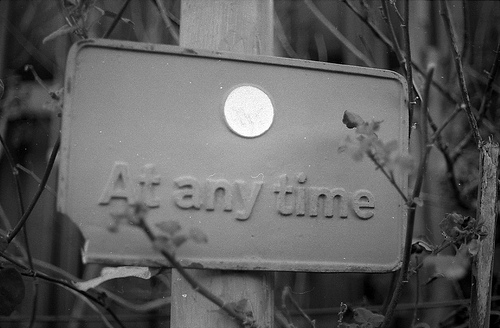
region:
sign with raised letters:
[32, 25, 457, 290]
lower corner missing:
[50, 190, 95, 275]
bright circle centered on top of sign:
[200, 80, 282, 142]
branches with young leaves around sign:
[26, 36, 466, 301]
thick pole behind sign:
[155, 6, 315, 316]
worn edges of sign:
[65, 32, 420, 277]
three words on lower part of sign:
[97, 155, 379, 230]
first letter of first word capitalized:
[95, 155, 375, 230]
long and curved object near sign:
[460, 122, 496, 319]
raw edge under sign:
[58, 250, 165, 295]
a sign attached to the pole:
[54, 29, 416, 281]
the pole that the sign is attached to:
[163, 0, 300, 327]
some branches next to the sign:
[321, 7, 478, 324]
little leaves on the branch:
[99, 196, 197, 260]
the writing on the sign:
[89, 155, 379, 227]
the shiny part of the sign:
[220, 80, 280, 144]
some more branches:
[16, 148, 158, 326]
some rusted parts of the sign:
[68, 36, 208, 61]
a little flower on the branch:
[333, 289, 375, 326]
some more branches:
[51, 9, 192, 44]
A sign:
[73, 70, 343, 262]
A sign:
[168, 129, 328, 314]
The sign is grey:
[51, 29, 424, 294]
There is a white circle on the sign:
[208, 69, 268, 150]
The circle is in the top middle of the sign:
[211, 74, 291, 162]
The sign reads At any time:
[92, 140, 389, 254]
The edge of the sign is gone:
[41, 122, 160, 282]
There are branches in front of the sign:
[347, 15, 489, 312]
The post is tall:
[178, 6, 290, 319]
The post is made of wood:
[169, 0, 292, 317]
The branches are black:
[26, 13, 214, 309]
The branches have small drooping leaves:
[340, 89, 493, 304]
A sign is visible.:
[81, 48, 346, 270]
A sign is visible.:
[102, 101, 294, 323]